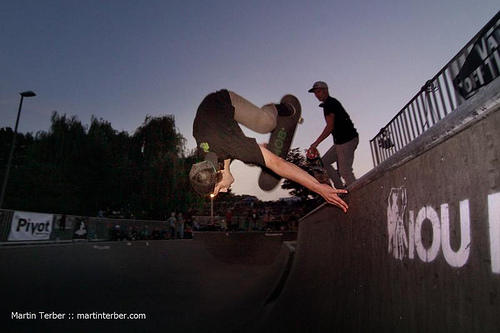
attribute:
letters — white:
[394, 205, 415, 261]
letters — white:
[411, 204, 443, 262]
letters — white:
[435, 191, 481, 271]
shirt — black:
[317, 95, 363, 147]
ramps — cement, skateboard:
[5, 85, 498, 332]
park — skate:
[4, 77, 495, 329]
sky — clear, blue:
[1, 3, 494, 199]